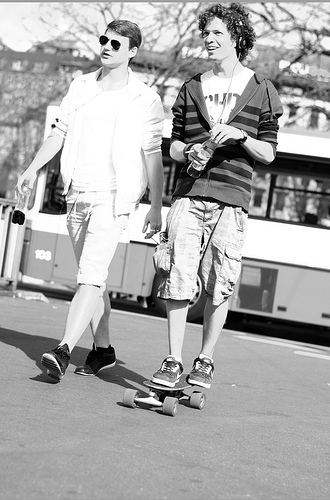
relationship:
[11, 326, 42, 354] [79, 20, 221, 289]
shadow of man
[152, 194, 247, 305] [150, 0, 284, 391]
shorts on boy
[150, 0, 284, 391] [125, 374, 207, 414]
boy on a skateboard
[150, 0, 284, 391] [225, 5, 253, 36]
boy with hair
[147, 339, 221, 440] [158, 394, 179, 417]
skateboard has wheel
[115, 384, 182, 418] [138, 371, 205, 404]
wheels of skateboard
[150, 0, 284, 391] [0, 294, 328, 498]
boy in street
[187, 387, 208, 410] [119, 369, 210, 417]
wheel on skateboard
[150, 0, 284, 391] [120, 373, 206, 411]
boy on skateboard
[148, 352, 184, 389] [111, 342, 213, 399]
right foot with shoe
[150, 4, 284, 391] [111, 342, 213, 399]
boy with shoe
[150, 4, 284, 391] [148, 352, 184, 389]
boy with right foot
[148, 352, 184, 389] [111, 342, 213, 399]
right foot in shoe